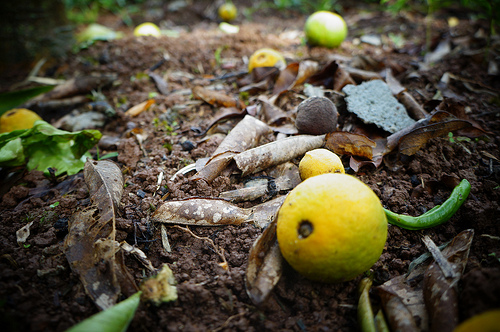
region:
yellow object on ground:
[248, 163, 394, 283]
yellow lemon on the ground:
[265, 159, 397, 269]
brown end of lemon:
[300, 217, 320, 231]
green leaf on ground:
[405, 167, 472, 235]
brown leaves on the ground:
[96, 178, 243, 254]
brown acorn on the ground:
[286, 92, 347, 139]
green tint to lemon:
[329, 217, 393, 274]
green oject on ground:
[308, 4, 354, 46]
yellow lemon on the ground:
[244, 49, 284, 79]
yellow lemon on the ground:
[0, 105, 45, 129]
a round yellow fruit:
[271, 172, 401, 280]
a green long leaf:
[379, 169, 473, 239]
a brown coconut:
[291, 90, 339, 137]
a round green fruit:
[297, 5, 352, 48]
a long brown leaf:
[156, 191, 255, 228]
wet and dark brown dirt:
[3, 0, 493, 322]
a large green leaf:
[3, 112, 94, 177]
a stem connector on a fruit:
[297, 215, 322, 245]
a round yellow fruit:
[299, 146, 344, 180]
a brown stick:
[16, 71, 109, 111]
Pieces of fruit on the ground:
[7, 8, 400, 283]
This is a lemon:
[292, 140, 356, 177]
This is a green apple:
[291, 3, 358, 56]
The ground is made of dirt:
[8, 5, 493, 325]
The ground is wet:
[5, 6, 483, 329]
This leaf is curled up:
[389, 175, 480, 228]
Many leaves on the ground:
[5, 66, 467, 330]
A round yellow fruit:
[274, 162, 396, 273]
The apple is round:
[300, 3, 357, 50]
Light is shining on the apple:
[314, 11, 348, 32]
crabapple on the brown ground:
[261, 157, 396, 268]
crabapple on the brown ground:
[296, 132, 349, 174]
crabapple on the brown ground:
[246, 34, 282, 74]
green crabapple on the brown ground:
[297, 7, 363, 52]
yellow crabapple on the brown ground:
[130, 17, 172, 45]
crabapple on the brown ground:
[4, 98, 61, 136]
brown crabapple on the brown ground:
[280, 89, 358, 141]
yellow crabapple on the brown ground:
[218, 0, 255, 26]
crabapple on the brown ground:
[431, 9, 473, 29]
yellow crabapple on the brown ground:
[257, 177, 404, 277]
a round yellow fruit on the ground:
[1, 108, 41, 139]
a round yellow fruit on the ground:
[277, 171, 387, 277]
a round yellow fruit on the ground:
[132, 21, 159, 40]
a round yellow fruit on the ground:
[217, 3, 235, 18]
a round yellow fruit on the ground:
[248, 49, 282, 74]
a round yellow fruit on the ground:
[304, 9, 342, 46]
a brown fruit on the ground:
[298, 95, 331, 127]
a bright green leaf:
[377, 180, 470, 225]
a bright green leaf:
[3, 122, 95, 180]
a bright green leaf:
[65, 293, 148, 330]